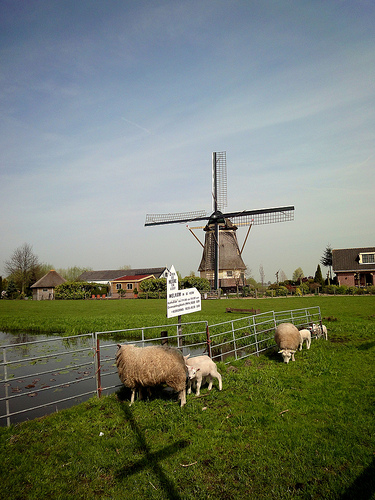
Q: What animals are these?
A: Sheep.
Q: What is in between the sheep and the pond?
A: A fence.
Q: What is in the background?
A: A windmill.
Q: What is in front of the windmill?
A: A grassy field.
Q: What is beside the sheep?
A: A metal fence.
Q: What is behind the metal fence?
A: A pond.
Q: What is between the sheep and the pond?
A: A metal fence.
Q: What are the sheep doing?
A: Eating grass.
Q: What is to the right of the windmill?
A: A house.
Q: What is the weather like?
A: Sunny.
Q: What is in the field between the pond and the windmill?
A: A feeding trough.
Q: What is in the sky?
A: Thin clouds.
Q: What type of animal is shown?
A: Sheep.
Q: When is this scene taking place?
A: Daytime.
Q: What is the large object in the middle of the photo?
A: Windmill.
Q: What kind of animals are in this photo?
A: Sheep.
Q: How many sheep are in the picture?
A: Six.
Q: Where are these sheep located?
A: Field.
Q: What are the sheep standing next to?
A: Fence.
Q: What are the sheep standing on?
A: Grass.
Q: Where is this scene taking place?
A: On a dutch farm.